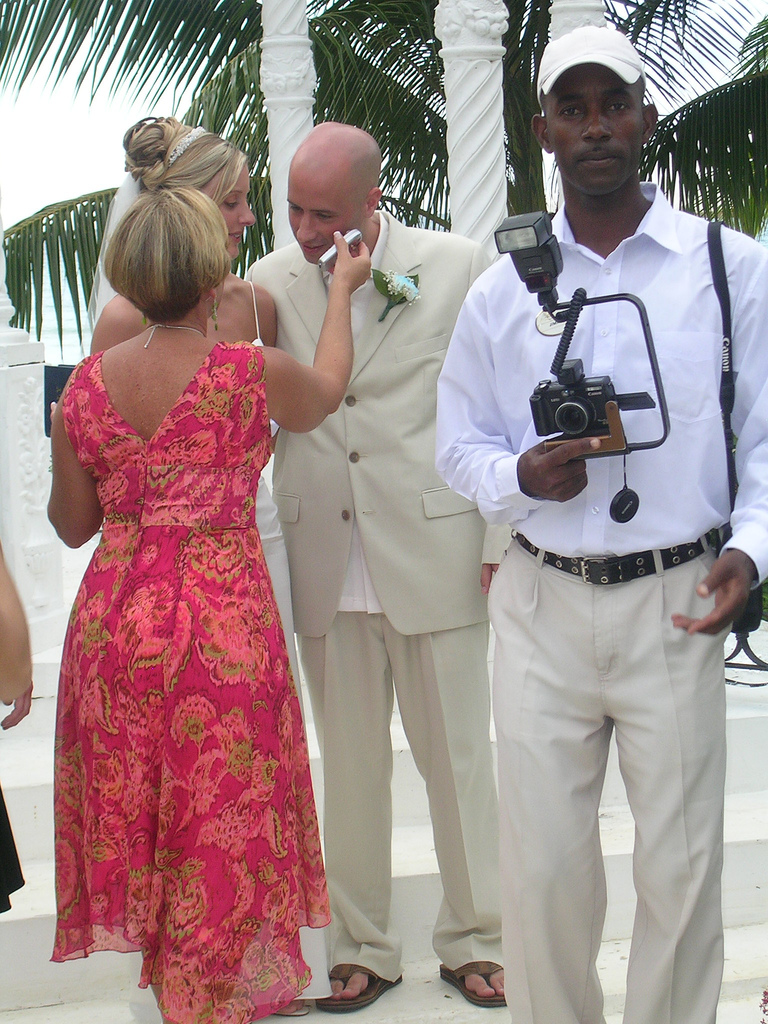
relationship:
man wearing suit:
[253, 120, 510, 1013] [247, 207, 512, 1019]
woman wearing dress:
[40, 183, 387, 1016] [90, 283, 291, 1009]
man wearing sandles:
[253, 120, 510, 1013] [311, 946, 518, 1021]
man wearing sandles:
[253, 120, 510, 1013] [307, 952, 506, 1007]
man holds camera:
[458, 50, 759, 819] [489, 205, 672, 524]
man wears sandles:
[253, 120, 510, 1013] [312, 938, 516, 1015]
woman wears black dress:
[0, 520, 40, 921] [0, 779, 29, 918]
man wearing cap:
[459, 51, 760, 820] [521, 28, 663, 117]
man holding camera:
[459, 51, 760, 820] [481, 186, 667, 529]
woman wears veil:
[73, 167, 380, 667] [84, 168, 146, 329]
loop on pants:
[650, 545, 668, 580] [493, 545, 734, 1021]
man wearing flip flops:
[253, 120, 510, 1013] [309, 951, 518, 1013]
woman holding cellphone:
[40, 182, 387, 1015] [314, 226, 366, 267]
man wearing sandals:
[253, 120, 510, 1013] [317, 949, 507, 1006]